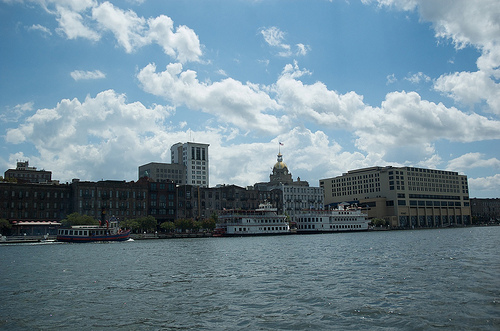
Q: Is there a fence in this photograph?
A: No, there are no fences.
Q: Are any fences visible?
A: No, there are no fences.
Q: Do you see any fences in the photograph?
A: No, there are no fences.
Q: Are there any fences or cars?
A: No, there are no fences or cars.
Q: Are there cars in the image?
A: No, there are no cars.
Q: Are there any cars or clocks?
A: No, there are no cars or clocks.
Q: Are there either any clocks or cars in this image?
A: No, there are no cars or clocks.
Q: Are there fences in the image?
A: No, there are no fences.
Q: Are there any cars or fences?
A: No, there are no fences or cars.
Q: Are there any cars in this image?
A: No, there are no cars.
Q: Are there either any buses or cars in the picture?
A: No, there are no cars or buses.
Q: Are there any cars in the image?
A: No, there are no cars.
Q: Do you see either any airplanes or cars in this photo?
A: No, there are no cars or airplanes.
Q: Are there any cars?
A: No, there are no cars.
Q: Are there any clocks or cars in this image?
A: No, there are no cars or clocks.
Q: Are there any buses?
A: No, there are no buses.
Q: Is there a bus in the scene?
A: No, there are no buses.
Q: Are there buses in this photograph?
A: No, there are no buses.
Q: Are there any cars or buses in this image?
A: No, there are no buses or cars.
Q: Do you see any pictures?
A: No, there are no pictures.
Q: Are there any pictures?
A: No, there are no pictures.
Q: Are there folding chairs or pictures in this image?
A: No, there are no pictures or folding chairs.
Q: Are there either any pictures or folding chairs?
A: No, there are no pictures or folding chairs.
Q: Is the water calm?
A: Yes, the water is calm.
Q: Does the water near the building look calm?
A: Yes, the water is calm.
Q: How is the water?
A: The water is calm.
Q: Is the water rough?
A: No, the water is calm.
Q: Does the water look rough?
A: No, the water is calm.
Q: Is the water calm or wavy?
A: The water is calm.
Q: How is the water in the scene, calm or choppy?
A: The water is calm.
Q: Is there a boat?
A: Yes, there is a boat.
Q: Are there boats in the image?
A: Yes, there is a boat.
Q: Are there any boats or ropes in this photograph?
A: Yes, there is a boat.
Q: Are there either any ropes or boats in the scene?
A: Yes, there is a boat.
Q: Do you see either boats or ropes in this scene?
A: Yes, there is a boat.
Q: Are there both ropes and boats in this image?
A: No, there is a boat but no ropes.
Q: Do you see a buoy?
A: No, there are no buoys.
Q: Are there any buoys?
A: No, there are no buoys.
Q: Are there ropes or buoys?
A: No, there are no buoys or ropes.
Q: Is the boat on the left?
A: Yes, the boat is on the left of the image.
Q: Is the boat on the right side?
A: No, the boat is on the left of the image.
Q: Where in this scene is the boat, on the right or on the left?
A: The boat is on the left of the image.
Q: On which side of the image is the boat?
A: The boat is on the left of the image.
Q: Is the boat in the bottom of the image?
A: Yes, the boat is in the bottom of the image.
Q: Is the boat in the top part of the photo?
A: No, the boat is in the bottom of the image.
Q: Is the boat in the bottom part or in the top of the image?
A: The boat is in the bottom of the image.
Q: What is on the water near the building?
A: The boat is on the water.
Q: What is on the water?
A: The boat is on the water.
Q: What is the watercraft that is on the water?
A: The watercraft is a boat.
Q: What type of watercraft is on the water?
A: The watercraft is a boat.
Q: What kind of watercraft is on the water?
A: The watercraft is a boat.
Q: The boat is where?
A: The boat is on the water.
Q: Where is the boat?
A: The boat is on the water.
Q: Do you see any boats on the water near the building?
A: Yes, there is a boat on the water.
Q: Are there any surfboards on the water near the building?
A: No, there is a boat on the water.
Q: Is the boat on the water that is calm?
A: Yes, the boat is on the water.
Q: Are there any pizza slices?
A: No, there are no pizza slices.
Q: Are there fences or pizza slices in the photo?
A: No, there are no pizza slices or fences.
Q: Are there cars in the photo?
A: No, there are no cars.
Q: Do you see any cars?
A: No, there are no cars.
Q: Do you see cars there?
A: No, there are no cars.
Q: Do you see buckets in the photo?
A: No, there are no buckets.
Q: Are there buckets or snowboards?
A: No, there are no buckets or snowboards.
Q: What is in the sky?
A: The clouds are in the sky.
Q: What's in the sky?
A: The clouds are in the sky.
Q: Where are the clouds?
A: The clouds are in the sky.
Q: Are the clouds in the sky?
A: Yes, the clouds are in the sky.